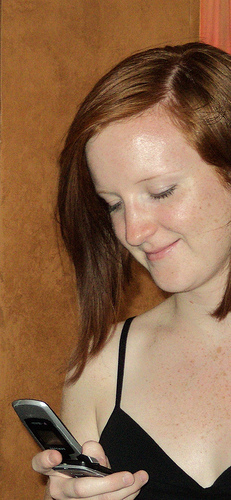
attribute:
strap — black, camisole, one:
[112, 311, 135, 412]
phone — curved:
[74, 448, 113, 474]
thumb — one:
[80, 436, 108, 470]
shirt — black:
[116, 411, 230, 483]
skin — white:
[165, 329, 219, 430]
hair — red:
[109, 50, 229, 152]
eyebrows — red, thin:
[98, 169, 176, 206]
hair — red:
[62, 57, 230, 297]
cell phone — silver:
[7, 402, 122, 481]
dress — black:
[94, 335, 230, 494]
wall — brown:
[2, 8, 114, 100]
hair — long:
[46, 49, 229, 352]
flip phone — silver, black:
[24, 400, 126, 485]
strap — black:
[98, 320, 152, 408]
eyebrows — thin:
[133, 168, 167, 191]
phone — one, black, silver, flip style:
[11, 399, 115, 477]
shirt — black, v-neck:
[97, 315, 229, 498]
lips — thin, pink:
[141, 237, 180, 261]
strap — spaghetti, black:
[114, 316, 134, 407]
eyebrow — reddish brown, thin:
[133, 172, 171, 184]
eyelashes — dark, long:
[147, 184, 176, 201]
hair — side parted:
[52, 42, 229, 389]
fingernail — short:
[47, 451, 58, 464]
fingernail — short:
[122, 472, 133, 485]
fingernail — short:
[136, 469, 149, 482]